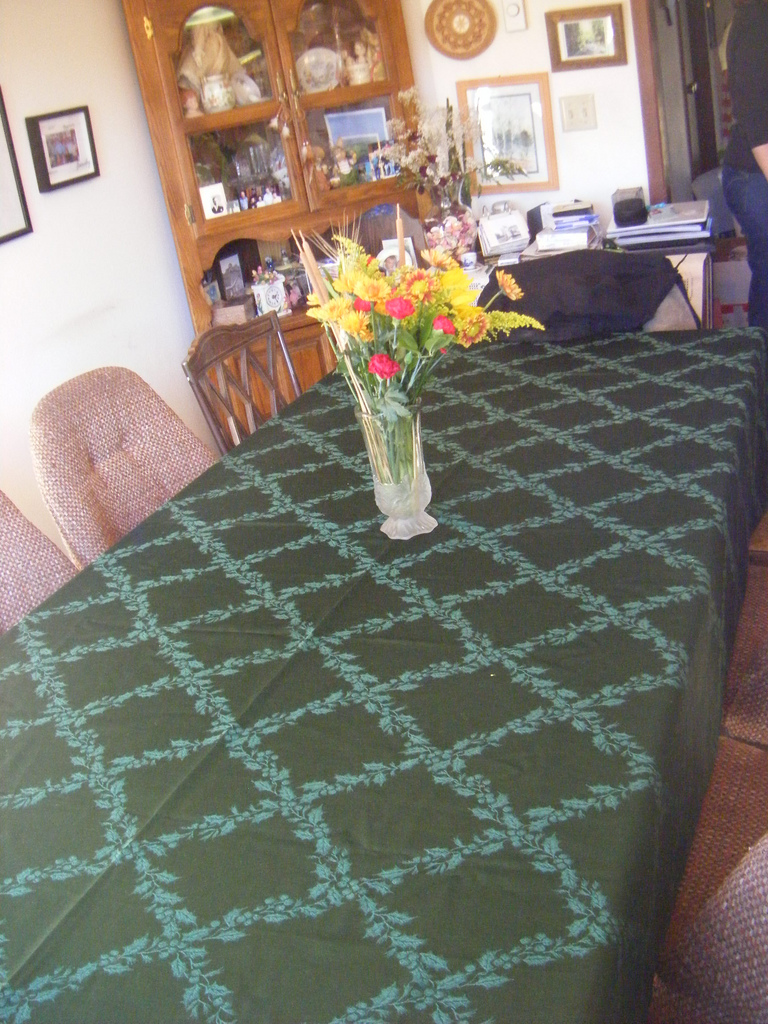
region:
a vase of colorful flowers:
[272, 209, 542, 565]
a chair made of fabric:
[9, 347, 237, 588]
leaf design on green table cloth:
[88, 725, 413, 1021]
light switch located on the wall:
[529, 63, 643, 171]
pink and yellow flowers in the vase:
[276, 225, 542, 469]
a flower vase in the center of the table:
[330, 384, 466, 558]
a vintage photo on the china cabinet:
[170, 160, 269, 229]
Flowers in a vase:
[261, 192, 540, 551]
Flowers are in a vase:
[270, 201, 539, 547]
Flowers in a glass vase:
[262, 196, 565, 548]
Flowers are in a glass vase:
[262, 192, 564, 549]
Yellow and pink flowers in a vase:
[283, 200, 556, 551]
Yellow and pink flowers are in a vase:
[265, 192, 546, 548]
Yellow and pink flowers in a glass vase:
[292, 198, 543, 545]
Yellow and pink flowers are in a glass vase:
[270, 190, 568, 547]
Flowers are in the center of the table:
[265, 176, 564, 552]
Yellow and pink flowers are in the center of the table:
[275, 194, 565, 549]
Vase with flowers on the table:
[305, 231, 547, 552]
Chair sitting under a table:
[35, 368, 214, 556]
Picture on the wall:
[25, 108, 102, 189]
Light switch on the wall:
[555, 89, 605, 135]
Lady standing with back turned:
[718, 3, 766, 326]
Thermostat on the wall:
[500, 0, 535, 44]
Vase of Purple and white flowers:
[383, 89, 474, 270]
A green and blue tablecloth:
[1, 543, 657, 1016]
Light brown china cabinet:
[122, 4, 436, 214]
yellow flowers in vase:
[285, 215, 541, 540]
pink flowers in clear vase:
[336, 283, 464, 557]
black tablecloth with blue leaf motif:
[21, 324, 767, 1008]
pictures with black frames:
[2, 65, 111, 254]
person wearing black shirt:
[715, 5, 765, 319]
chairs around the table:
[9, 240, 766, 1022]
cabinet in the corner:
[132, 5, 443, 429]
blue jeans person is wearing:
[723, 162, 762, 321]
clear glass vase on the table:
[355, 410, 439, 538]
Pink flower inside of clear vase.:
[370, 350, 408, 389]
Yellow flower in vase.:
[488, 271, 526, 313]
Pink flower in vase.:
[384, 295, 423, 332]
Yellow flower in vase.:
[336, 274, 365, 293]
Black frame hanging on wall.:
[24, 105, 112, 185]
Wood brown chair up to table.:
[171, 328, 304, 411]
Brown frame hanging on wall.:
[449, 72, 572, 185]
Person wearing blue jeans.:
[723, 157, 766, 264]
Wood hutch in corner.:
[119, 31, 432, 271]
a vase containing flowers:
[283, 201, 551, 554]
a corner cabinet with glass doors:
[124, 3, 480, 439]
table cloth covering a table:
[0, 331, 765, 1022]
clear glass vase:
[348, 395, 453, 546]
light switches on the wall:
[553, 89, 607, 144]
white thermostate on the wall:
[494, 0, 536, 46]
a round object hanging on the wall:
[409, 0, 507, 61]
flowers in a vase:
[288, 189, 554, 571]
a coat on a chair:
[438, 231, 708, 393]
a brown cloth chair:
[10, 340, 233, 574]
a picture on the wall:
[25, 81, 100, 208]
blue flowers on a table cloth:
[127, 747, 562, 983]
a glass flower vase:
[337, 374, 467, 557]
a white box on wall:
[497, 0, 544, 34]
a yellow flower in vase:
[447, 264, 472, 327]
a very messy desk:
[478, 183, 717, 272]